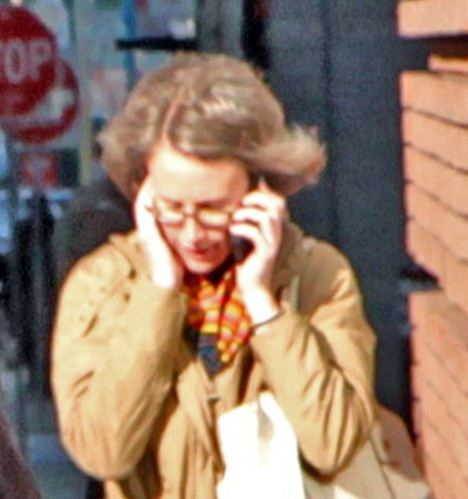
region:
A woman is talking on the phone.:
[36, 37, 439, 497]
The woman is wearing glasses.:
[134, 152, 263, 285]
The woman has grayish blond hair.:
[69, 49, 365, 232]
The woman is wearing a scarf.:
[145, 236, 306, 374]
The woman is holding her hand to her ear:
[110, 151, 301, 310]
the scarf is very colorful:
[146, 231, 275, 387]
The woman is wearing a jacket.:
[36, 217, 418, 494]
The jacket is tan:
[35, 219, 429, 494]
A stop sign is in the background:
[0, 0, 56, 123]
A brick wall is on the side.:
[384, 1, 466, 494]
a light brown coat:
[50, 222, 374, 498]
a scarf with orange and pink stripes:
[177, 264, 255, 377]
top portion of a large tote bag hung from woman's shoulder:
[215, 237, 432, 497]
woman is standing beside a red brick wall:
[52, 0, 467, 497]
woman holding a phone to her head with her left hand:
[225, 167, 286, 291]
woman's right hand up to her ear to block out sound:
[133, 173, 185, 290]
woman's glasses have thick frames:
[144, 203, 233, 229]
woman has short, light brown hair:
[95, 52, 326, 201]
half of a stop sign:
[0, 4, 58, 119]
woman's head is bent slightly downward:
[94, 52, 325, 273]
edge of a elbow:
[110, 456, 130, 483]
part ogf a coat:
[199, 432, 221, 480]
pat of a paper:
[213, 399, 229, 440]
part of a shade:
[254, 401, 262, 447]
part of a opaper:
[237, 410, 263, 476]